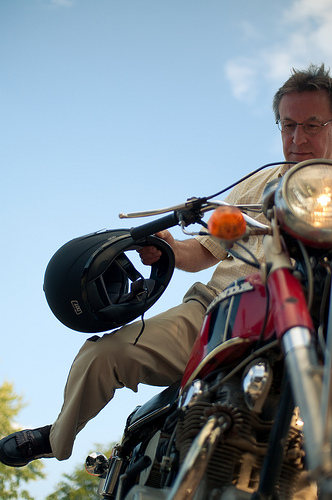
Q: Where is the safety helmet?
A: In person hand.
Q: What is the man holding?
A: A helmet.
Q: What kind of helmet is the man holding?
A: A black motorbike helmet.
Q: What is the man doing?
A: He is getting off his bike.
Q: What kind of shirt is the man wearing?
A: A checkered shirt.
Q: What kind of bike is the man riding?
A: A red and black motorcycle.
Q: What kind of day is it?
A: A nice, clear day.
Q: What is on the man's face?
A: Glasses.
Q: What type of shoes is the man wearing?
A: Black leather shoes.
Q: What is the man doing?
A: Getting on the motorcycle.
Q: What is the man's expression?
A: Concentration.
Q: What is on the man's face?
A: Eyeglasses.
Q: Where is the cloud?
A: Above the man's head.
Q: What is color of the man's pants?
A: Beige.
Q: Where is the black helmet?
A: In the man's right hand.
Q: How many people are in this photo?
A: 1.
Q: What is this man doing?
A: Getting off his cycle.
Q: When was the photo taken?
A: Daytime.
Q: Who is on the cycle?
A: A man.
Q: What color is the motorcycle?
A: Red and black.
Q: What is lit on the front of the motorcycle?
A: Headlight.